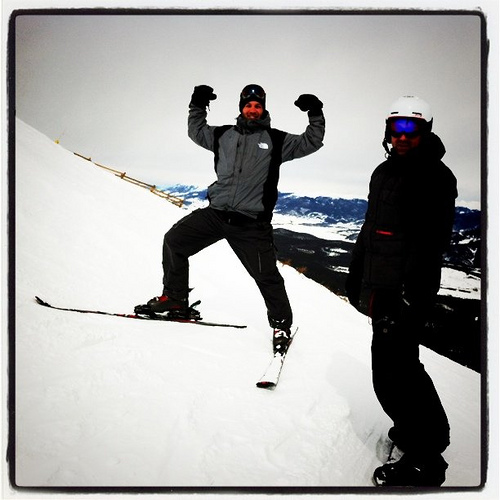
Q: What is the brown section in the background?
A: A fence.